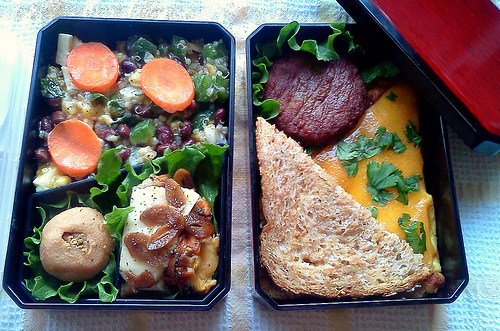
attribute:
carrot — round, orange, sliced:
[71, 41, 117, 91]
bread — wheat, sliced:
[257, 119, 363, 287]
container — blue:
[248, 20, 470, 306]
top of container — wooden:
[361, 3, 499, 99]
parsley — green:
[372, 164, 408, 198]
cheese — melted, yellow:
[378, 103, 406, 135]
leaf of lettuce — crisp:
[101, 161, 135, 231]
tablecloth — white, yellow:
[7, 310, 481, 330]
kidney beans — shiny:
[158, 126, 178, 155]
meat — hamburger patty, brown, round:
[263, 52, 368, 141]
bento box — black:
[17, 5, 468, 320]